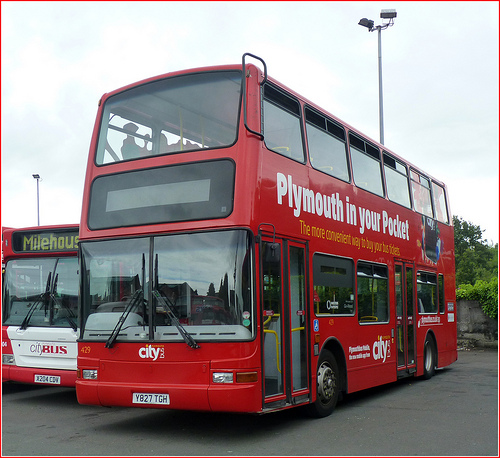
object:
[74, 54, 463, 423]
bus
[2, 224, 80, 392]
bus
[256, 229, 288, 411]
door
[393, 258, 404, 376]
door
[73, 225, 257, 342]
windshield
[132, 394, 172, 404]
license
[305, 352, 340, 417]
wheel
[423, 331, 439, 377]
wheel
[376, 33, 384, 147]
pole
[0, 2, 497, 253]
sky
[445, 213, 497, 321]
tree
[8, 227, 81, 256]
sign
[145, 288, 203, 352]
wiper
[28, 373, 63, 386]
plate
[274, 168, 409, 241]
sign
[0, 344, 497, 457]
street